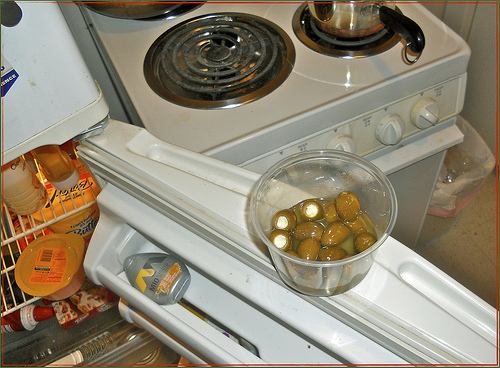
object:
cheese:
[306, 203, 316, 215]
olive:
[335, 191, 363, 222]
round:
[240, 149, 399, 268]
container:
[247, 148, 400, 297]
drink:
[121, 250, 193, 306]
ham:
[14, 233, 86, 303]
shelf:
[5, 163, 94, 245]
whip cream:
[4, 298, 57, 336]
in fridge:
[2, 121, 170, 366]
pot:
[303, 2, 425, 65]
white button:
[372, 113, 405, 145]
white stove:
[79, 4, 466, 191]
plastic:
[442, 170, 454, 183]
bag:
[426, 117, 494, 221]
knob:
[411, 100, 444, 132]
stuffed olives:
[299, 200, 325, 222]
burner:
[155, 16, 280, 102]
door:
[76, 118, 494, 365]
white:
[27, 73, 69, 116]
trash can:
[423, 110, 495, 219]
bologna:
[15, 230, 92, 301]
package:
[14, 233, 84, 298]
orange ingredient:
[31, 247, 66, 284]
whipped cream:
[1, 303, 52, 334]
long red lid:
[33, 304, 56, 322]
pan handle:
[358, 11, 429, 81]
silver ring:
[402, 39, 426, 65]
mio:
[146, 276, 161, 292]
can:
[3, 305, 55, 333]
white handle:
[323, 136, 359, 160]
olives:
[294, 233, 325, 259]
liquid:
[341, 239, 355, 251]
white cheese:
[275, 217, 287, 227]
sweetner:
[0, 145, 46, 216]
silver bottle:
[122, 251, 192, 306]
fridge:
[0, 3, 493, 361]